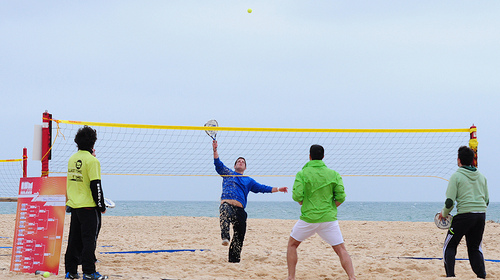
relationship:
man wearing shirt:
[205, 120, 296, 269] [216, 159, 255, 206]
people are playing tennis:
[72, 105, 499, 259] [8, 24, 499, 269]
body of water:
[140, 201, 166, 209] [127, 200, 156, 217]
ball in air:
[245, 7, 261, 25] [192, 26, 218, 36]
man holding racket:
[205, 120, 296, 269] [193, 118, 226, 145]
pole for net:
[36, 112, 59, 173] [180, 118, 290, 138]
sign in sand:
[9, 176, 68, 275] [363, 226, 402, 248]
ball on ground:
[245, 7, 261, 25] [167, 263, 225, 274]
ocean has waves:
[147, 202, 184, 214] [364, 205, 394, 216]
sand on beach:
[363, 226, 402, 248] [136, 224, 172, 244]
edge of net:
[460, 126, 471, 136] [180, 118, 290, 138]